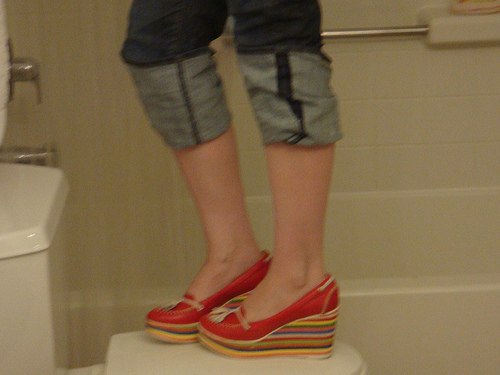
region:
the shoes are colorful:
[139, 222, 371, 372]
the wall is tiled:
[359, 69, 448, 231]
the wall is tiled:
[390, 60, 497, 145]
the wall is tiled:
[369, 147, 481, 250]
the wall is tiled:
[391, 27, 460, 140]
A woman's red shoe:
[196, 275, 349, 367]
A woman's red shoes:
[140, 239, 356, 371]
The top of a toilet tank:
[0, 150, 77, 373]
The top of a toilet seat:
[83, 298, 368, 373]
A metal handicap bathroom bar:
[314, 7, 499, 51]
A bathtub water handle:
[6, 30, 51, 120]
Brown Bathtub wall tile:
[67, 115, 139, 242]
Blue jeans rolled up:
[105, 20, 362, 186]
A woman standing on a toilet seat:
[104, 14, 358, 371]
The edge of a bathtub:
[358, 243, 493, 360]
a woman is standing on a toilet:
[117, 1, 346, 363]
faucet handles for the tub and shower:
[5, 38, 66, 169]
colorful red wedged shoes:
[139, 248, 342, 363]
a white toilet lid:
[105, 329, 378, 373]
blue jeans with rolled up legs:
[118, 0, 354, 160]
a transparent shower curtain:
[7, 2, 196, 347]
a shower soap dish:
[415, 2, 499, 46]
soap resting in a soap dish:
[449, 0, 498, 20]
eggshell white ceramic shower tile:
[376, 99, 430, 146]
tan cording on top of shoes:
[158, 297, 255, 332]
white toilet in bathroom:
[5, 161, 367, 372]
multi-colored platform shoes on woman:
[134, 260, 350, 373]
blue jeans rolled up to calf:
[117, 0, 355, 146]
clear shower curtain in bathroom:
[9, 4, 191, 374]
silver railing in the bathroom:
[203, 18, 442, 68]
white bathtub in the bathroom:
[75, 179, 497, 371]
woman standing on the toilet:
[110, 0, 356, 364]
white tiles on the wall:
[340, 47, 498, 192]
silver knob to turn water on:
[5, 45, 52, 121]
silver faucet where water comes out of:
[10, 135, 77, 185]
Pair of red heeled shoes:
[138, 249, 343, 364]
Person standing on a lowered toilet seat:
[94, 292, 379, 374]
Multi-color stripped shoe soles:
[193, 319, 348, 360]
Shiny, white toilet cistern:
[0, 155, 81, 372]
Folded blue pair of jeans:
[118, 3, 346, 154]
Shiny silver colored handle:
[0, 42, 50, 119]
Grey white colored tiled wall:
[342, 57, 489, 283]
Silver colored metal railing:
[317, 20, 432, 47]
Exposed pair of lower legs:
[162, 142, 362, 267]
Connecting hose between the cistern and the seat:
[61, 360, 108, 373]